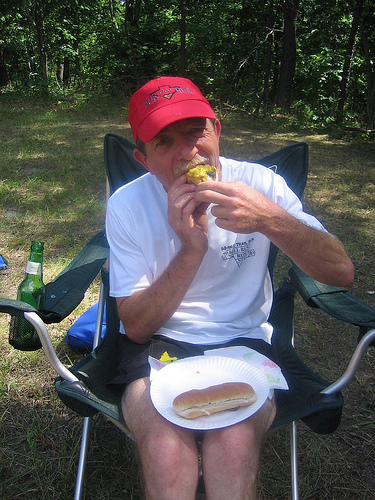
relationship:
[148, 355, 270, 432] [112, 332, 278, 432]
paper plate on lap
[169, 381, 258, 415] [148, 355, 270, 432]
hot dog bun on plate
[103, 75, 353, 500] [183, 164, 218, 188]
man holding food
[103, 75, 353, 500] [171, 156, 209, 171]
man has mustache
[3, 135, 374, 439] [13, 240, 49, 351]
chair holds beer bottle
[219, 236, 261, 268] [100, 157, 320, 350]
emblem on shirt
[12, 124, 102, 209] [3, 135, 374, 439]
green grass behind chair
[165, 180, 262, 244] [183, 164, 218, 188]
hands holding food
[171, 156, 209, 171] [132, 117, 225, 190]
mustache on face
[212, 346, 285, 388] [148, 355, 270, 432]
napkin under plate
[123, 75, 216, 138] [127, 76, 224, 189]
baseball cap on head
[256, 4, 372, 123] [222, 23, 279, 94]
trees have leaves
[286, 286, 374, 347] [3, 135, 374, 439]
arm rest on chair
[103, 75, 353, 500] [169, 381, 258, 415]
man eating hotdog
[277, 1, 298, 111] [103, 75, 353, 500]
tree trunk behind man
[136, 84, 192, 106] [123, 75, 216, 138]
logo on cap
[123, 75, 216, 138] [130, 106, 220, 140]
cap with brim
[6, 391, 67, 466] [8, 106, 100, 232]
sparse grass on ground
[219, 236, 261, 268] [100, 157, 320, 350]
symbol on shirt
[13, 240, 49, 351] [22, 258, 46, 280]
bottle with label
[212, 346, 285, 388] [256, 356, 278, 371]
napkin with flower design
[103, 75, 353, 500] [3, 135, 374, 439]
man in chair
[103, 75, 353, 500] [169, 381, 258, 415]
man eating hot dog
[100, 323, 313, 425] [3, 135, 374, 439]
sitting on folding chair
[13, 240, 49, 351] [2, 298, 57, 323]
glass bottle in cup holder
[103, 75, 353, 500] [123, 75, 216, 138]
man wearing baseball cap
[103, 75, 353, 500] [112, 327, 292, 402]
man wearing shorts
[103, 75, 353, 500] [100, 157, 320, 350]
man wearing t-shirt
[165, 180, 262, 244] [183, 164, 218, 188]
holding a hot dog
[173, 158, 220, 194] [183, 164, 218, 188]
eating a hot dog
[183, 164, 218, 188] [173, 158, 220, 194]
hot dog being ate